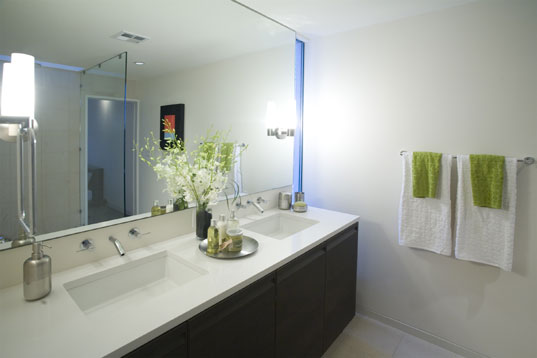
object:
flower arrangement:
[132, 119, 249, 240]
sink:
[63, 251, 210, 317]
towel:
[412, 151, 442, 198]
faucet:
[109, 236, 125, 256]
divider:
[78, 51, 126, 228]